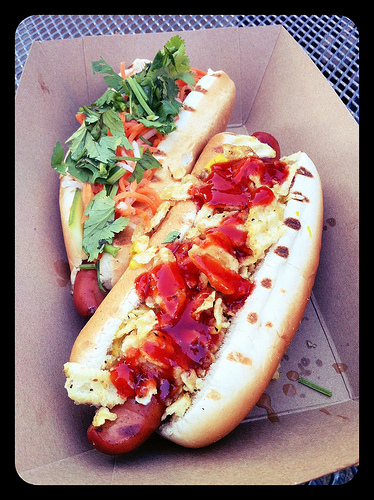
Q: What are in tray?
A: Hotdogs.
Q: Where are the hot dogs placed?
A: In a box.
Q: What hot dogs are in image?
A: Buns.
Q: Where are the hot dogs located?
A: Inside a brown box.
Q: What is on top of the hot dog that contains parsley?
A: Shredded carrots.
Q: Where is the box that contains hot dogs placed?
A: On top of a metal table.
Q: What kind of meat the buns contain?
A: Brown hot dogs.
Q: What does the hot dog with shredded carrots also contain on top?
A: Lettuce.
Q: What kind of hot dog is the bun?
A: A loaded hot dog.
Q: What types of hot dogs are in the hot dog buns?
A: Loaded hot dogs.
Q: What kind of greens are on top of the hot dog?
A: Leafy greens.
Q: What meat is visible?
A: Hot dogs.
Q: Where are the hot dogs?
A: In the buns.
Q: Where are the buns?
A: In the brown box.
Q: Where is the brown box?
A: On the wire table.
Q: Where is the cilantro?
A: On the left hot dog.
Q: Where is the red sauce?
A: On the right hotdog.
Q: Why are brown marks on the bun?
A: It was grilled.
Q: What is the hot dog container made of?
A: Cardboard.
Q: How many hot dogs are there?
A: 2.